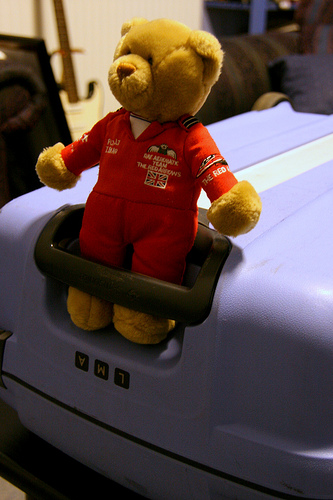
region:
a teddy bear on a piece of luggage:
[11, 4, 318, 493]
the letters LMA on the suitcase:
[56, 313, 142, 409]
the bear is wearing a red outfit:
[102, 127, 189, 274]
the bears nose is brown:
[118, 52, 134, 82]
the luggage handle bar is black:
[39, 240, 215, 330]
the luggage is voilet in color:
[281, 244, 300, 392]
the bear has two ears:
[65, 48, 233, 117]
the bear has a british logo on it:
[141, 165, 174, 192]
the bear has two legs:
[65, 264, 161, 364]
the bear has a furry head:
[86, 48, 201, 134]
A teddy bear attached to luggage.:
[115, 28, 220, 237]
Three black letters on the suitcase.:
[67, 348, 135, 393]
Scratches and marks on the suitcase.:
[88, 454, 170, 490]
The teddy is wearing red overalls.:
[76, 113, 188, 235]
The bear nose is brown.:
[114, 55, 132, 81]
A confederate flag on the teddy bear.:
[133, 154, 187, 186]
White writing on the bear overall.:
[102, 135, 126, 157]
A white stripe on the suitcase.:
[230, 136, 330, 208]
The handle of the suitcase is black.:
[41, 242, 222, 326]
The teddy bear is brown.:
[70, 22, 240, 226]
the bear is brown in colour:
[43, 17, 250, 261]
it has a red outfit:
[59, 83, 264, 308]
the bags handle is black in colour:
[35, 196, 237, 344]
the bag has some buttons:
[53, 343, 154, 403]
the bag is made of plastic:
[180, 296, 316, 472]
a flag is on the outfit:
[137, 156, 181, 206]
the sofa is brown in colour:
[228, 27, 287, 93]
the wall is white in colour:
[78, 12, 109, 63]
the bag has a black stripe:
[54, 392, 247, 499]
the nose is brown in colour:
[112, 57, 143, 87]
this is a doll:
[44, 24, 249, 242]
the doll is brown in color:
[51, 19, 240, 242]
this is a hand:
[196, 159, 265, 241]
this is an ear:
[188, 29, 221, 76]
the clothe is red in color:
[118, 192, 173, 244]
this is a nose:
[115, 59, 134, 76]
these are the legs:
[74, 311, 160, 334]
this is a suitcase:
[222, 294, 302, 490]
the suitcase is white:
[237, 257, 314, 370]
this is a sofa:
[237, 43, 266, 83]